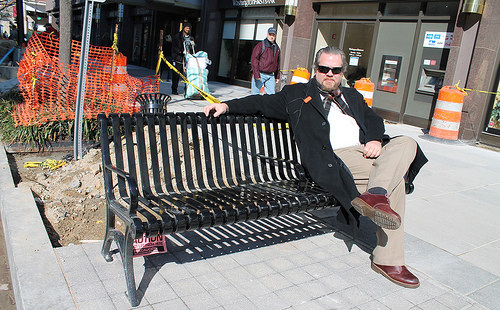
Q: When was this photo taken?
A: Daytime.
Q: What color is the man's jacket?
A: Black.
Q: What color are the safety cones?
A: Orange and white.